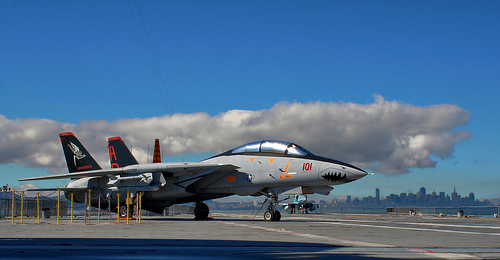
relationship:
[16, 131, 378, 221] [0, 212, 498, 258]
jet on landing strip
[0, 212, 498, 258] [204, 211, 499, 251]
landing strip has stripes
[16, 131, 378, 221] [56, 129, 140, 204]
jet has tail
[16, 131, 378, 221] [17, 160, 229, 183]
jet has wing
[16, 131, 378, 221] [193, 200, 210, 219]
jet has tire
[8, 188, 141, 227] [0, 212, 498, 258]
poles on landing strip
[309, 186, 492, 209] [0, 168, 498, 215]
buildings in distance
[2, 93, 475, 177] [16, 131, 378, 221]
cloud behind jet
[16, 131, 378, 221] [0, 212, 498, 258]
jet at landing strip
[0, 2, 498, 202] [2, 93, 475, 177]
sky has cloud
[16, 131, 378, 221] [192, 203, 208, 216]
jet has wheel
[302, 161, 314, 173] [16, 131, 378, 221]
writing on jet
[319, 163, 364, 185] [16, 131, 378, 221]
teeth on jet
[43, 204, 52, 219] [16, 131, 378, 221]
trash can behind jet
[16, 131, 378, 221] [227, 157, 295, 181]
jet has stickers